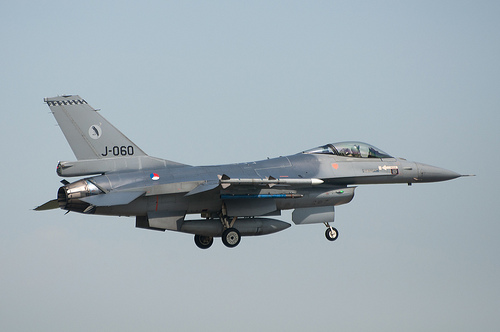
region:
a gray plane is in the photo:
[27, 61, 478, 306]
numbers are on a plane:
[30, 109, 243, 188]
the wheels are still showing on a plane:
[172, 183, 364, 326]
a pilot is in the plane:
[287, 113, 405, 189]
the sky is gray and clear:
[55, 215, 177, 315]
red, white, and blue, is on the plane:
[138, 166, 195, 233]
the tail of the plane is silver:
[48, 173, 137, 266]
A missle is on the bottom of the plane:
[141, 203, 388, 275]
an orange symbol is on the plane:
[314, 157, 346, 178]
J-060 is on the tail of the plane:
[87, 125, 247, 207]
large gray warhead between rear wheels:
[177, 211, 292, 236]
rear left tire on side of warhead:
[191, 231, 211, 246]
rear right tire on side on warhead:
[220, 225, 237, 245]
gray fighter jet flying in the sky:
[30, 91, 476, 246]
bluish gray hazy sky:
[0, 0, 496, 325]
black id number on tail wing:
[97, 140, 132, 155]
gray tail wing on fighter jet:
[40, 90, 152, 155]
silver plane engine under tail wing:
[55, 176, 102, 208]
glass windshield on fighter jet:
[301, 140, 391, 156]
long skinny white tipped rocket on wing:
[215, 170, 321, 190]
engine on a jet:
[56, 180, 92, 212]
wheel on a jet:
[221, 225, 241, 245]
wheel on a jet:
[325, 225, 339, 240]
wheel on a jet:
[192, 233, 214, 247]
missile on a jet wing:
[215, 169, 323, 190]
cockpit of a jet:
[302, 140, 391, 160]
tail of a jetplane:
[45, 94, 160, 169]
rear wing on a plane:
[77, 185, 142, 205]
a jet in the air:
[33, 93, 478, 245]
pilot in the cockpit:
[349, 143, 362, 156]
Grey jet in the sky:
[36, 54, 465, 305]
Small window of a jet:
[312, 126, 395, 165]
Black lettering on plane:
[92, 141, 152, 158]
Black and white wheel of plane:
[321, 224, 346, 248]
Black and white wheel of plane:
[221, 225, 246, 249]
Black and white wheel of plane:
[182, 231, 206, 248]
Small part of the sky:
[33, 273, 83, 323]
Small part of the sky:
[427, 293, 457, 328]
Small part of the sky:
[353, 274, 377, 324]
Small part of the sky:
[298, 286, 328, 322]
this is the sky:
[166, 23, 233, 71]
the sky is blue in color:
[157, 13, 257, 69]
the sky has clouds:
[307, 260, 427, 295]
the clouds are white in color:
[366, 233, 454, 303]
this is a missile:
[176, 218, 289, 235]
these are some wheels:
[216, 220, 340, 246]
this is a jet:
[37, 77, 466, 244]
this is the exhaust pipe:
[55, 186, 93, 207]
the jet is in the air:
[37, 92, 472, 227]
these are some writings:
[96, 144, 148, 159]